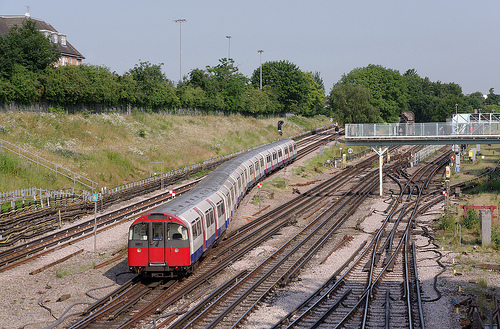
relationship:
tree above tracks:
[252, 60, 305, 117] [30, 142, 467, 328]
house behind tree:
[0, 17, 83, 70] [0, 18, 60, 76]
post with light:
[175, 18, 187, 87] [175, 18, 186, 24]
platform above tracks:
[341, 122, 499, 195] [30, 142, 467, 328]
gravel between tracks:
[246, 195, 395, 328] [30, 142, 467, 328]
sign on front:
[149, 211, 166, 219] [128, 214, 191, 280]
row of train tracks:
[81, 192, 423, 213] [30, 142, 467, 328]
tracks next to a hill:
[30, 142, 467, 328] [0, 105, 334, 217]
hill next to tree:
[0, 105, 334, 217] [252, 60, 305, 117]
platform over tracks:
[341, 122, 499, 195] [30, 142, 467, 328]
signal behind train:
[276, 120, 284, 135] [124, 138, 305, 270]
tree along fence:
[252, 60, 305, 117] [1, 99, 327, 117]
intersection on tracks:
[354, 194, 447, 262] [30, 142, 467, 328]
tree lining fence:
[252, 60, 305, 117] [1, 99, 327, 117]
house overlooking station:
[0, 17, 83, 70] [0, 106, 495, 327]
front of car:
[128, 214, 191, 280] [126, 196, 217, 285]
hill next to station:
[0, 105, 334, 217] [0, 106, 495, 327]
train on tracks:
[124, 138, 305, 270] [30, 142, 467, 328]